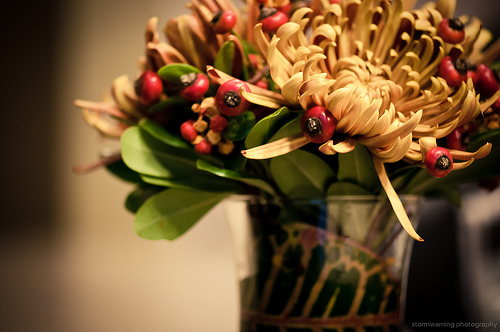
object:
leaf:
[119, 121, 198, 187]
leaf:
[136, 111, 191, 152]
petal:
[277, 21, 300, 62]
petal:
[247, 21, 270, 53]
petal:
[261, 35, 289, 87]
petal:
[372, 161, 425, 241]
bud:
[305, 118, 323, 135]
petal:
[240, 134, 310, 158]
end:
[224, 92, 237, 107]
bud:
[221, 88, 241, 109]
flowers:
[77, 0, 500, 246]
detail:
[250, 228, 397, 315]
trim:
[300, 253, 342, 317]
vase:
[222, 184, 417, 332]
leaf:
[132, 193, 219, 243]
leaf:
[195, 150, 277, 198]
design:
[241, 219, 397, 329]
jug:
[219, 195, 427, 332]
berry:
[440, 55, 471, 86]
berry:
[475, 65, 500, 93]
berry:
[200, 12, 250, 32]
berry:
[135, 69, 164, 107]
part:
[115, 61, 181, 114]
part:
[170, 70, 206, 102]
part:
[431, 47, 469, 85]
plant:
[72, 0, 498, 239]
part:
[461, 50, 493, 95]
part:
[457, 111, 480, 137]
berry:
[424, 145, 455, 178]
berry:
[301, 108, 338, 143]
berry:
[440, 17, 469, 45]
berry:
[257, 10, 291, 32]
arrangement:
[67, 1, 499, 239]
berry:
[169, 69, 212, 102]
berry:
[216, 78, 248, 115]